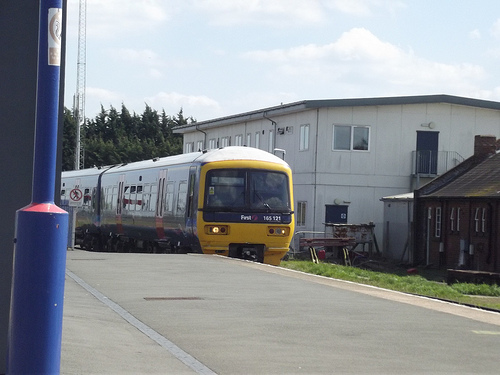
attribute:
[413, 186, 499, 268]
house — brown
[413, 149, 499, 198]
roof — brown